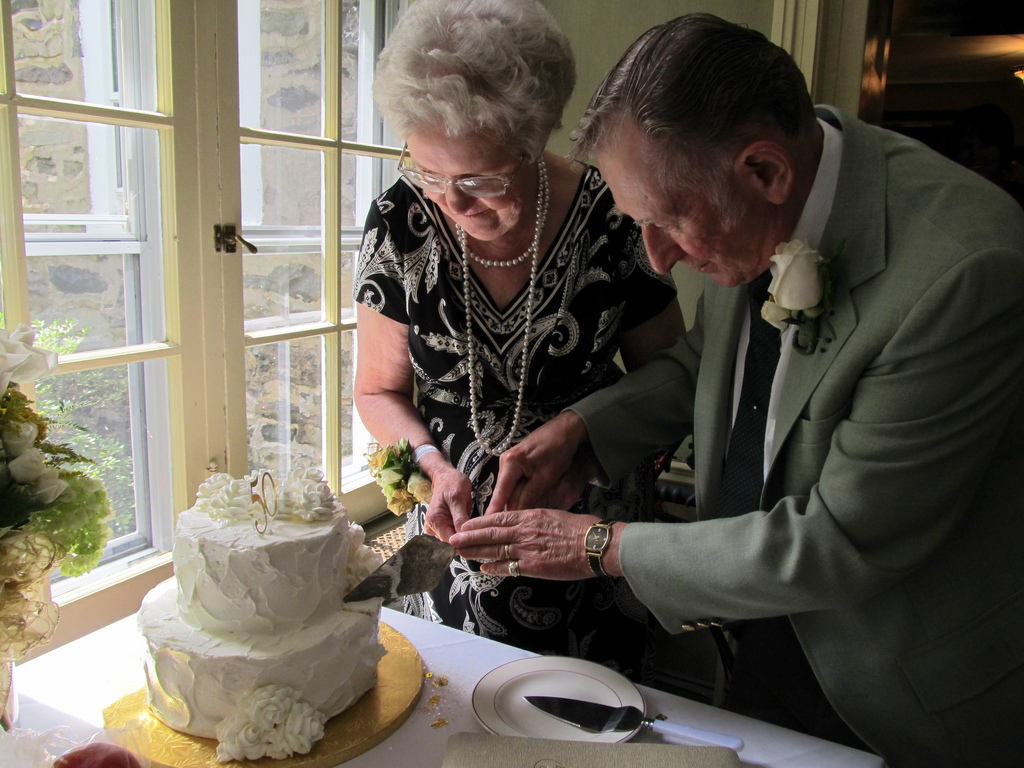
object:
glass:
[13, 0, 160, 113]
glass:
[334, 11, 381, 146]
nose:
[641, 226, 687, 274]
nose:
[444, 183, 476, 215]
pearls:
[455, 155, 553, 455]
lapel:
[759, 118, 888, 509]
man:
[451, 13, 1024, 767]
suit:
[559, 103, 1024, 768]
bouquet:
[0, 323, 110, 726]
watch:
[584, 519, 617, 577]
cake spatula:
[476, 656, 657, 743]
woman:
[353, 0, 684, 673]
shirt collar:
[785, 113, 846, 247]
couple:
[351, 0, 1024, 768]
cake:
[137, 470, 387, 762]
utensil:
[343, 534, 456, 603]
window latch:
[214, 224, 257, 254]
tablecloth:
[0, 605, 885, 768]